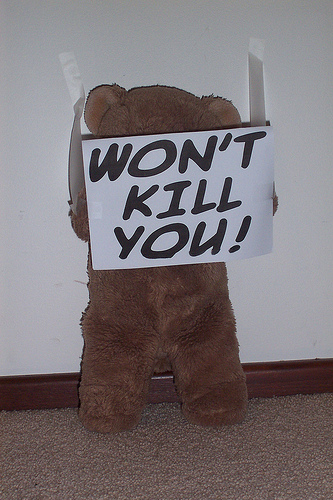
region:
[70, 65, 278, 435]
A stuffed upright animal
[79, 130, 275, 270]
The 'won't kill you' sticker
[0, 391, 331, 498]
A carpeted flow surface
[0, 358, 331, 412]
The wooden wall base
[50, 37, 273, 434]
The stuffed animal on the wall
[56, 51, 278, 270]
A white printed sticker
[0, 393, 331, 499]
The woolen brown carpet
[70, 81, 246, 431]
The taped stuffed animal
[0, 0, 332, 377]
A white painted wall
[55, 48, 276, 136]
The tape on the wall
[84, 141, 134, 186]
The letter is black.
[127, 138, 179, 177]
The letter is black.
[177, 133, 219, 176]
The letter is black.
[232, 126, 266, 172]
The letter is black.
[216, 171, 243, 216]
The letter is black.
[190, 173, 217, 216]
The letter is black.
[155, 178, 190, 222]
The letter is black.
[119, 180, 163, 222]
The letter is black.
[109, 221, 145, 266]
The letter is black.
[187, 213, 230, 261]
The letter is black.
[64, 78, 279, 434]
brown stuffed bear holding up a sign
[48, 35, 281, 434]
stuffed bear with a sign covering its face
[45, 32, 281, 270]
sign held up by semi clear tape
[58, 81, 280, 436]
small stuffed bear and a sign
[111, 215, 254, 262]
black marker print reading YOU!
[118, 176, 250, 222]
black marker print reading KILL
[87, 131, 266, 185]
marker print on a sign reading WON'T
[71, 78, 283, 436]
stuffed bear holding a Won't Kill You sign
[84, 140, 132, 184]
black print of the letter W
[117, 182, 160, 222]
black marker letter print K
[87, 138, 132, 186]
This is a letter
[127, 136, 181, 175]
This is a letter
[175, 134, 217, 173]
This is a letter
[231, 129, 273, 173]
This is a letter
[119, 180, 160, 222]
This is a letter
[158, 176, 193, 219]
This is a letter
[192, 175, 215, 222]
This is a letter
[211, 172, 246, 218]
This is a letter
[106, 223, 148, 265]
This is a letter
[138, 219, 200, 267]
This is a letter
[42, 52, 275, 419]
this is a teddy bear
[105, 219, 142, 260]
a letter on a note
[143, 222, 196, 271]
a letter on a note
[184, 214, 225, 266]
a letter on a note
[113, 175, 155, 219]
a letter on a note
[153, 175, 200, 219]
a letter on a note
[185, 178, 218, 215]
a letter on a note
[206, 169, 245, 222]
a letter on a note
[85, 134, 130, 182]
a letter on a note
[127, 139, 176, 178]
a letter on a note